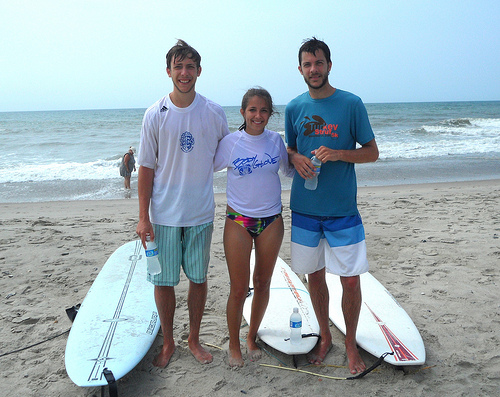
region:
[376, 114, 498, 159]
Wave in the water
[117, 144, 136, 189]
Woman standing in water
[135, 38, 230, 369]
Man standing by friends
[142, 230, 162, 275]
Water bottle that man is holding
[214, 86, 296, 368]
Woman wearing a bikini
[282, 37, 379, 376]
Man standing next to friends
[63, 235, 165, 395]
White surfboard in sand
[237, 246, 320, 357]
White surfboard in sand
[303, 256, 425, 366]
White surfboard in sand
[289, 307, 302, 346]
Water bottle on surfboard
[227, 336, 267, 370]
the lady is bare footed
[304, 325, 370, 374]
the man is bare footed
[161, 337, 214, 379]
the man is bare footed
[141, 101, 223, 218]
the t-shirt is white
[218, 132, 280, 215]
the tshirt is white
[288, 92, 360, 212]
the tshirt is blue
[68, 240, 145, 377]
the srfing board is blue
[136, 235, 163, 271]
the man is holding a bottle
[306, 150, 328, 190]
the man is holding a bottle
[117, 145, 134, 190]
the woman is at the background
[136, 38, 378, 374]
three people standing on the beach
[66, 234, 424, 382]
three surfboards on the sand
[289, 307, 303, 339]
a bottle of water on a surfboard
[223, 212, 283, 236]
woman wearing a bikini bottom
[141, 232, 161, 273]
man holding a bottle of water with one hand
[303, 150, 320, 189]
man holding a bottle of water with two hands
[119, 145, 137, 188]
a woman with her feet in the ocean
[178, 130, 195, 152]
a blue logo on a white shirt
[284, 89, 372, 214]
man wearing a blue T-shirt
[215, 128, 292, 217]
woman wearing a white shirt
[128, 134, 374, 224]
these are three people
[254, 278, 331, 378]
this is a bottle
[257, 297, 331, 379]
the bottle is clear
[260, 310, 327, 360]
the bottle is plastic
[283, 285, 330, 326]
this is a cap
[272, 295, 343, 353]
the cap is white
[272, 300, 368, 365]
the cap is plastic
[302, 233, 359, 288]
these are some shorts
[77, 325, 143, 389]
this is a board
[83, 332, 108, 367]
the board is white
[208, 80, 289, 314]
the lady is in the middle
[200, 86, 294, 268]
the lady is short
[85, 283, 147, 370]
this is a surf board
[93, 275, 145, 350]
the board is white in color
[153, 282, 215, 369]
the man is bare footed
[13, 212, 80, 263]
this is the beach sand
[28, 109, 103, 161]
this is the sea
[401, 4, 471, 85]
this is the sky